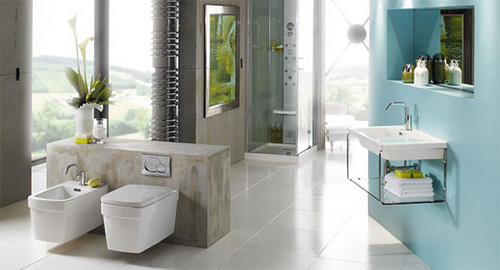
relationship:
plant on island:
[65, 7, 113, 142] [43, 135, 229, 247]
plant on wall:
[63, 15, 115, 110] [192, 1, 248, 168]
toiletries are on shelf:
[398, 51, 467, 82] [376, 69, 488, 104]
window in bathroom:
[313, 3, 374, 128] [3, 2, 495, 267]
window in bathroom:
[109, 3, 154, 140] [3, 2, 495, 267]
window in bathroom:
[30, 2, 100, 153] [3, 2, 495, 267]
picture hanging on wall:
[205, 3, 240, 115] [181, 2, 248, 166]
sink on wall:
[337, 103, 473, 220] [367, 6, 484, 265]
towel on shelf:
[382, 175, 431, 198] [339, 133, 449, 209]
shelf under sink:
[350, 171, 444, 205] [348, 125, 446, 162]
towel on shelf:
[382, 175, 437, 190] [343, 166, 448, 210]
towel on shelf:
[382, 175, 431, 198] [350, 171, 450, 208]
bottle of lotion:
[413, 56, 429, 86] [386, 61, 439, 131]